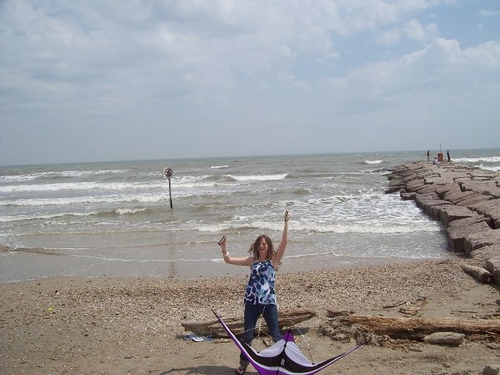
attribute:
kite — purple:
[216, 309, 363, 369]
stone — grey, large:
[452, 216, 489, 224]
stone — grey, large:
[447, 221, 493, 238]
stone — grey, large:
[440, 204, 475, 216]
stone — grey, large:
[474, 247, 498, 258]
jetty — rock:
[375, 137, 495, 312]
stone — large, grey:
[425, 198, 481, 225]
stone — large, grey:
[466, 170, 492, 190]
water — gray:
[0, 148, 499, 279]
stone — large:
[401, 170, 420, 184]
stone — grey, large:
[405, 177, 425, 190]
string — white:
[243, 324, 270, 338]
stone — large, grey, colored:
[439, 183, 476, 200]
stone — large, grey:
[444, 218, 493, 252]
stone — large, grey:
[363, 152, 487, 268]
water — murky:
[202, 163, 314, 230]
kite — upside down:
[205, 290, 363, 372]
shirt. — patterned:
[249, 271, 274, 297]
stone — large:
[444, 200, 469, 224]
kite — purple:
[214, 309, 368, 374]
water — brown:
[2, 152, 469, 283]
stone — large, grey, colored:
[422, 177, 455, 188]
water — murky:
[237, 192, 281, 222]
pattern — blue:
[243, 258, 278, 306]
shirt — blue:
[247, 255, 276, 308]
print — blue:
[249, 267, 271, 300]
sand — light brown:
[0, 263, 499, 373]